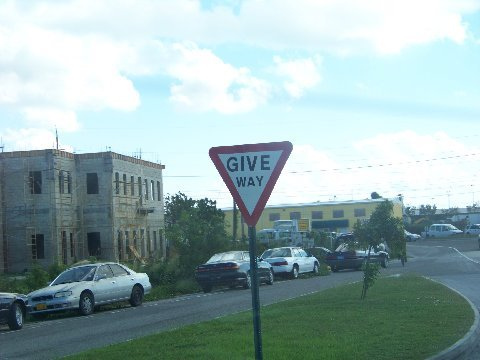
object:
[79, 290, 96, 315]
tire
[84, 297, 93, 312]
hubcap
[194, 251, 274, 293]
car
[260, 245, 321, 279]
car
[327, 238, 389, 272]
car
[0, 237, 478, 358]
road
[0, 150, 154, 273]
scaffold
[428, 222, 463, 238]
van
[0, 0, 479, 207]
clouds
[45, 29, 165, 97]
sky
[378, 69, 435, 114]
sky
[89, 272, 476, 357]
grass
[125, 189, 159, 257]
metal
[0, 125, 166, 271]
building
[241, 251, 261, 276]
door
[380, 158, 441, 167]
wires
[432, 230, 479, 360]
roadway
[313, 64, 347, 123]
sky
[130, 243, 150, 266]
staircase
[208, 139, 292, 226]
black sign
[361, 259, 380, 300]
small green tree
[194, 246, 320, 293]
black and white cars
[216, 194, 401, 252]
side of building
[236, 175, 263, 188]
that spell way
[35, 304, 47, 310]
license plate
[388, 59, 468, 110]
sky is blue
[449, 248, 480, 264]
white line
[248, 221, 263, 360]
sign post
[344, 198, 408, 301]
green tree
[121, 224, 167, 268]
yellow metal scaffol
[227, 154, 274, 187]
black lettering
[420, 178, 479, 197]
wires in the sky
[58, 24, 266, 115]
white fluffy clouds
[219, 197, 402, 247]
building is yellow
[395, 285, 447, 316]
flowers on the grass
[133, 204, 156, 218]
scaffolding for the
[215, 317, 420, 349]
curb for the island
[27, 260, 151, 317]
blue parked car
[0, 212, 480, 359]
parking lot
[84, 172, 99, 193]
without a window